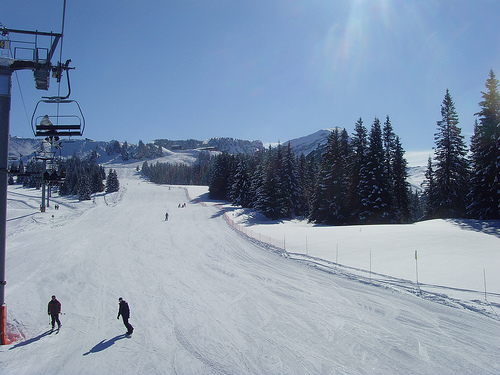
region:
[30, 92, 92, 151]
a person in a ski lift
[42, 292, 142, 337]
two people skiing in the snow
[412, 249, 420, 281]
a pole in the snow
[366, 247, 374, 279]
a pole in the snow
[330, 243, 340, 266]
a pole in the snow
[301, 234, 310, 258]
a pole in the snow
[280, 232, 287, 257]
a pole in the snow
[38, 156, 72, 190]
people in a ski lift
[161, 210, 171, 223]
a person skiing in the distance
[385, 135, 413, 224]
a tree covered in snow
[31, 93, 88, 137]
A ski lift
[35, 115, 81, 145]
A person sitting on a ski lift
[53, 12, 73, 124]
The cable holding the ski lift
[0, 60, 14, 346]
A metal support beam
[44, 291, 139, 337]
Two people on the snow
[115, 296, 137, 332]
A snowboarder in dark clothing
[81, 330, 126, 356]
The shadow of the snowboarder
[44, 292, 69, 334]
A skier on skis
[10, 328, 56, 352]
The shadow of the skier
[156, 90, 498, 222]
Tall pine trees lining the slope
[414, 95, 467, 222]
this is a tree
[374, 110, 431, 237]
this is a tree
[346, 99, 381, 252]
this is a tree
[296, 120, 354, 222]
this is a tree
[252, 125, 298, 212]
this is a tree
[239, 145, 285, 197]
this is a tree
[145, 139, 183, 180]
this is a tree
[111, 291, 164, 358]
this is a person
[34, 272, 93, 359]
this is a person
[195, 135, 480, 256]
tall green evergreen trees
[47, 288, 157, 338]
people skiing on snow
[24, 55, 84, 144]
ski lift above people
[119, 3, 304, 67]
blue and clear sky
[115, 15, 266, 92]
no clouds in sky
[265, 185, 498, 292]
poles on edge of course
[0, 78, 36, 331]
grey and orange pole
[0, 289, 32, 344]
orange base of pole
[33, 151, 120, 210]
trees in far distance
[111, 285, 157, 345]
person wears dark clothes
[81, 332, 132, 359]
person skiing on snow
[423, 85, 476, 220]
tall green evergreen tree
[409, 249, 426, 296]
upright thin pole in snow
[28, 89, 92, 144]
metal air lift